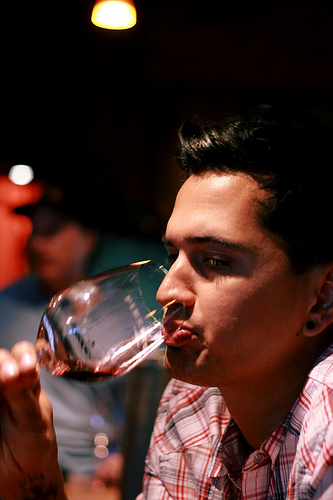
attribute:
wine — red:
[33, 302, 118, 391]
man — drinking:
[0, 118, 331, 498]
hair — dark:
[169, 98, 331, 280]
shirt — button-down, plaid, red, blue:
[134, 349, 330, 500]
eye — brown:
[187, 239, 237, 295]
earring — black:
[299, 318, 320, 336]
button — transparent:
[250, 452, 273, 469]